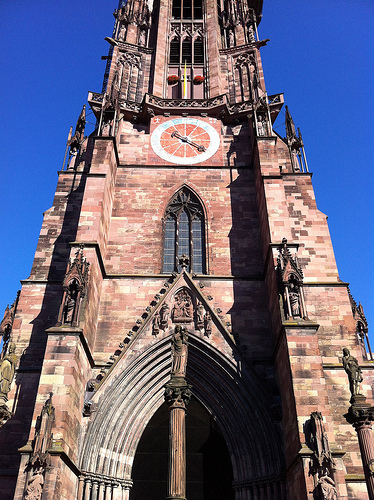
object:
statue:
[342, 347, 363, 395]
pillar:
[52, 0, 314, 198]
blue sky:
[1, 1, 108, 302]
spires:
[62, 104, 86, 171]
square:
[149, 118, 224, 167]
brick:
[57, 352, 71, 387]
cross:
[179, 253, 190, 268]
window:
[182, 23, 191, 63]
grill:
[182, 38, 192, 62]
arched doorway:
[130, 392, 234, 499]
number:
[181, 157, 188, 164]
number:
[172, 118, 177, 124]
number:
[162, 123, 169, 129]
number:
[183, 118, 189, 124]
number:
[202, 125, 208, 130]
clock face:
[148, 116, 223, 167]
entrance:
[128, 386, 234, 498]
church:
[0, 0, 374, 500]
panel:
[171, 288, 196, 322]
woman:
[171, 325, 189, 378]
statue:
[170, 324, 189, 384]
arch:
[78, 330, 286, 500]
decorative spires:
[284, 104, 309, 172]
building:
[0, 0, 374, 500]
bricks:
[106, 173, 155, 273]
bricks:
[208, 169, 260, 269]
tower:
[0, 0, 374, 500]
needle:
[183, 59, 187, 99]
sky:
[262, 0, 373, 353]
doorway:
[75, 275, 283, 500]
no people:
[115, 348, 251, 498]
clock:
[148, 116, 222, 169]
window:
[161, 183, 207, 276]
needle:
[171, 131, 207, 152]